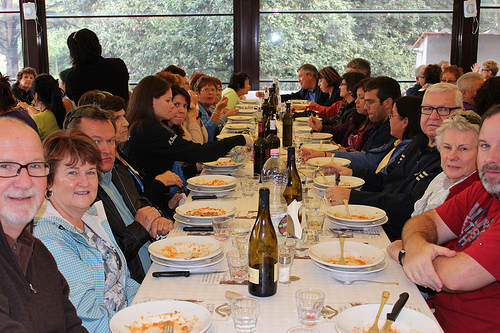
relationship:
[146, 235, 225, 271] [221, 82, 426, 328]
plate are on top of table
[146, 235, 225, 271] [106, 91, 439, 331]
plate on top of table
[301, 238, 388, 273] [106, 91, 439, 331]
plate on top of table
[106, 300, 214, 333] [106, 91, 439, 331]
plate on top of table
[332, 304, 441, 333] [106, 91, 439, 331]
plate on top of table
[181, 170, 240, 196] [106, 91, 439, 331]
plate on top of table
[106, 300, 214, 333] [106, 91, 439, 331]
plate on table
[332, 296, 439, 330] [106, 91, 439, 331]
plate on table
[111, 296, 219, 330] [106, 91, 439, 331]
plate on table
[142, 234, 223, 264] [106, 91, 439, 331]
plate on table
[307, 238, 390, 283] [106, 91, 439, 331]
plate on table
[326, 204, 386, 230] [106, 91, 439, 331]
plate on table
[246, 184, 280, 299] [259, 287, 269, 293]
bottle has part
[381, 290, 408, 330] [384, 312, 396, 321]
knife has part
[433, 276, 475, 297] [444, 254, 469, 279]
elbow has part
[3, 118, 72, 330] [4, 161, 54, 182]
man has glasses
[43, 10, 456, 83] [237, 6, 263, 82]
windows have trim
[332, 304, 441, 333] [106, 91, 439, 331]
plate on table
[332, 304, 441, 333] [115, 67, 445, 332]
plate aligned on table